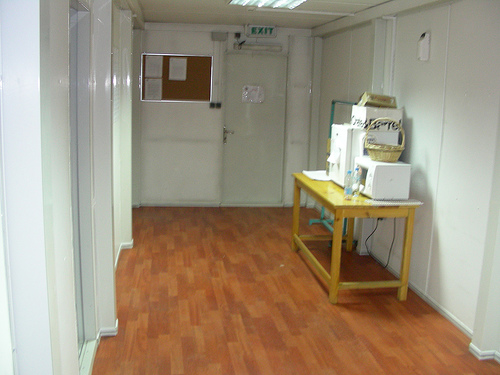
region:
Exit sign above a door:
[244, 22, 278, 40]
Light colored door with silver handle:
[216, 48, 293, 208]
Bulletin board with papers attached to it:
[138, 52, 214, 105]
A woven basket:
[362, 117, 407, 164]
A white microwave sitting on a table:
[351, 154, 412, 201]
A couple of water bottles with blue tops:
[342, 167, 364, 202]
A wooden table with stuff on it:
[289, 169, 424, 302]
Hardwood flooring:
[88, 204, 499, 374]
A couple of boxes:
[348, 91, 405, 132]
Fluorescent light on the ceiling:
[228, 0, 308, 11]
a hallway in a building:
[40, 22, 461, 349]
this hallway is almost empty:
[52, 22, 398, 293]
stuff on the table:
[305, 90, 416, 201]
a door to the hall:
[220, 35, 290, 210]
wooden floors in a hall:
[145, 210, 295, 367]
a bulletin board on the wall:
[131, 41, 237, 114]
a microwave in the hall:
[348, 156, 414, 206]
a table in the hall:
[280, 166, 416, 311]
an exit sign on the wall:
[233, 20, 284, 40]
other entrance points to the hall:
[18, 12, 156, 374]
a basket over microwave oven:
[358, 110, 405, 171]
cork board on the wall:
[120, 37, 270, 136]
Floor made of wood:
[111, 205, 483, 370]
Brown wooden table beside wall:
[289, 169, 422, 298]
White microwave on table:
[354, 202, 413, 212]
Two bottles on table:
[345, 168, 362, 200]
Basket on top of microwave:
[363, 116, 405, 160]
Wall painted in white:
[401, 5, 498, 354]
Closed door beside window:
[217, 55, 287, 207]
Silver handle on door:
[223, 125, 234, 141]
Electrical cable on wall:
[363, 220, 398, 265]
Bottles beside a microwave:
[343, 166, 366, 198]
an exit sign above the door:
[228, 8, 294, 45]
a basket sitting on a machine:
[364, 115, 410, 162]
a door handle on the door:
[218, 117, 243, 150]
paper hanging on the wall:
[409, 20, 447, 70]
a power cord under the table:
[359, 218, 412, 267]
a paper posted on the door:
[230, 62, 292, 134]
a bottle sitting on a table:
[334, 163, 369, 213]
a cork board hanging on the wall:
[137, 40, 224, 115]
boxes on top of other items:
[345, 74, 415, 143]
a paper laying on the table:
[298, 154, 335, 193]